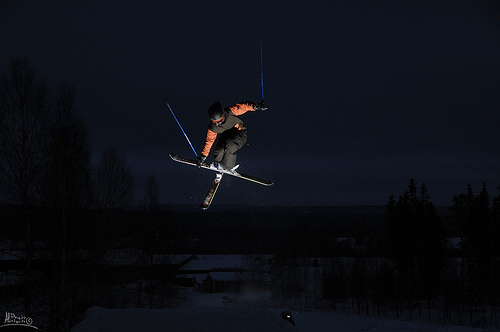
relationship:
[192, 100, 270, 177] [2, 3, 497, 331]
skier up in air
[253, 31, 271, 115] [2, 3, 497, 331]
pole up in air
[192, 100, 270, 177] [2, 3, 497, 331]
skier in air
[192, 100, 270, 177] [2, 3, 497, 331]
skier sailing through air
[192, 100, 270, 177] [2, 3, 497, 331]
skier jumping through air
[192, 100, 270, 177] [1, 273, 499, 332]
skier above groiund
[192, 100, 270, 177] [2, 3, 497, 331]
skier in mid air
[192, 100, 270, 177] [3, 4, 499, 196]
skier in sky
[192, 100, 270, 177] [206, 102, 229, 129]
skier wearing helmet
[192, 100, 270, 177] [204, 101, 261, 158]
skier wearing jacket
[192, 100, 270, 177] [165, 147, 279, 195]
skier wearing ski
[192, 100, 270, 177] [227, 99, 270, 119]
skier has arm